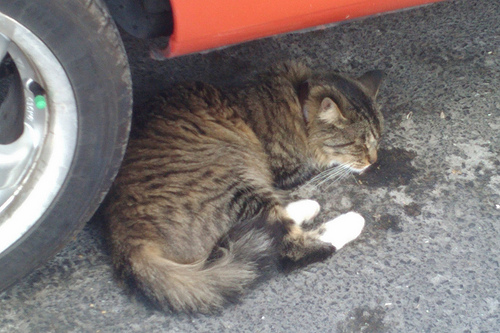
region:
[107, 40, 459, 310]
the cat is sleeping on the ground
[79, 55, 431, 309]
the cat is sleeping by the tire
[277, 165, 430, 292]
the cat has white feet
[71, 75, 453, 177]
the cat is in an oil spot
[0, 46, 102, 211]
the wheel has a green cap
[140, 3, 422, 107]
the car is red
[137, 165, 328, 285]
the cat is striped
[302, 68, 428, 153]
the cat has two ears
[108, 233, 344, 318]
the cat has a fluffy tail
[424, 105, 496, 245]
the cement is white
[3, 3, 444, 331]
a cat sleeping near a car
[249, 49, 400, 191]
eyes of cat are closed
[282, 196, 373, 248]
back feet of cat are white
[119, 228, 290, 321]
a long tail of cat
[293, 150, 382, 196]
white whiskers of cat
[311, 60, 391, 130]
pointy ears of cat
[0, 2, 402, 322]
cat is in front a wheel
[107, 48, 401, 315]
cat is brown with black stripes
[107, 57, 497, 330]
cat is lying on a road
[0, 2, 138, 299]
black rubber tire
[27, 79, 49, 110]
green and black plug on tire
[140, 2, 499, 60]
bottom of red metal car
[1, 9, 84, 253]
silver colored rim on tire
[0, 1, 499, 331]
black concrete ground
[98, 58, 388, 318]
furry brown and black cat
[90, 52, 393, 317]
black and brown cat with white feet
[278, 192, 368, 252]
white feet of brown and black cat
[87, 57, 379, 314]
cat sleeping on pavement ground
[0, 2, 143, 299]
old rubber tire on red car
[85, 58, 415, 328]
brown and tan cat lying under car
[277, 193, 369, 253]
white paws of cat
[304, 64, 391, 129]
two pointed ears of cat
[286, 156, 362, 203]
white whiskers on side of cat's face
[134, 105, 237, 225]
black stripes on side of cat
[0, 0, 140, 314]
black tire on cat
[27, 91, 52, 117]
green tire air cap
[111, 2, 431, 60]
bottom of red car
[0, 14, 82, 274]
metal rim inside of tire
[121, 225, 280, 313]
brown and tan cat tail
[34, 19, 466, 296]
a cat under a car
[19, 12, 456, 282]
the cat is under a tire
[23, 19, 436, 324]
the cat is near the tire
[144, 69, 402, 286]
the cat is brown with black stripes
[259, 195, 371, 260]
this cat has white legs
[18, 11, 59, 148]
this tire has a green nozzle cover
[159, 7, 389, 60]
the car is red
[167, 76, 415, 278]
the cat looks tired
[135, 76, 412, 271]
the cat is lying on the concrete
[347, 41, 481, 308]
messy concrete beneath the cat